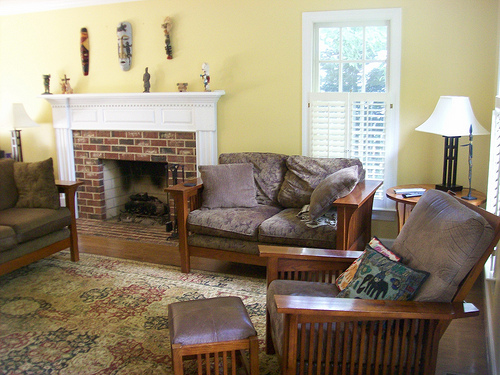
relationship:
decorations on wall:
[69, 20, 136, 81] [80, 21, 247, 106]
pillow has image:
[345, 232, 425, 308] [361, 274, 379, 281]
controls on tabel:
[390, 177, 447, 214] [418, 179, 494, 216]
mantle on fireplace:
[85, 90, 179, 148] [72, 126, 162, 214]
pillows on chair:
[344, 249, 408, 299] [307, 212, 467, 351]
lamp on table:
[395, 97, 467, 183] [390, 187, 432, 220]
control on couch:
[291, 203, 359, 237] [215, 155, 333, 222]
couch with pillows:
[215, 155, 333, 222] [344, 249, 408, 299]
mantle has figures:
[85, 90, 179, 148] [41, 67, 225, 107]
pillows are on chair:
[344, 249, 408, 299] [254, 184, 484, 360]